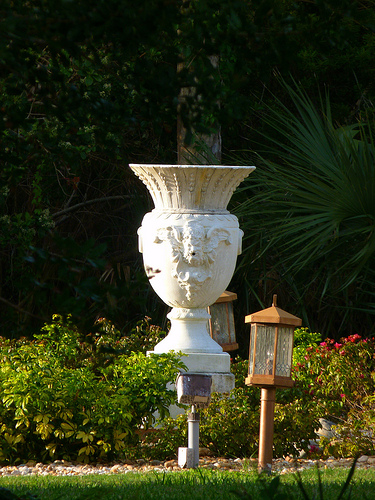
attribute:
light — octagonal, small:
[241, 288, 304, 470]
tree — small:
[1, 0, 371, 325]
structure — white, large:
[128, 161, 256, 433]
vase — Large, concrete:
[110, 143, 293, 446]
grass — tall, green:
[125, 473, 191, 498]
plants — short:
[317, 357, 367, 406]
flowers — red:
[316, 338, 349, 356]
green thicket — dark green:
[0, 0, 373, 341]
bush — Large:
[87, 352, 174, 461]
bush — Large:
[3, 310, 99, 444]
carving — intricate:
[158, 221, 232, 301]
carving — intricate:
[161, 217, 230, 319]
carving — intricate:
[158, 224, 233, 317]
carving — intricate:
[158, 214, 234, 320]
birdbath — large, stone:
[132, 162, 257, 373]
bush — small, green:
[9, 311, 177, 457]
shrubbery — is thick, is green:
[0, 312, 373, 464]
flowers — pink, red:
[330, 332, 360, 347]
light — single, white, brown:
[169, 361, 219, 443]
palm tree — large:
[179, 90, 374, 317]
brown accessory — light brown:
[241, 292, 306, 477]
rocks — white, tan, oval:
[0, 456, 374, 475]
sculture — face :
[184, 226, 205, 269]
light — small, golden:
[245, 287, 298, 477]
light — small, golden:
[210, 282, 242, 358]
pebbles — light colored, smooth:
[2, 464, 173, 475]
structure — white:
[116, 156, 248, 362]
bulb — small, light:
[266, 340, 285, 371]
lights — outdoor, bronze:
[190, 298, 299, 390]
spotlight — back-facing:
[168, 372, 210, 471]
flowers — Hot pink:
[319, 337, 359, 357]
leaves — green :
[287, 331, 372, 446]